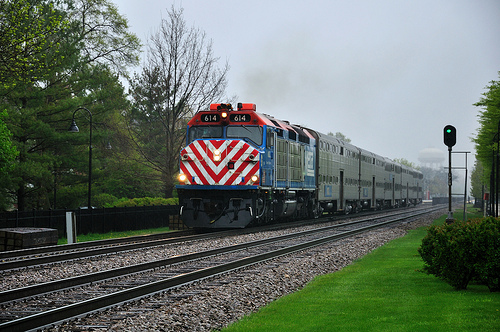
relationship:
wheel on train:
[310, 204, 324, 219] [176, 98, 431, 245]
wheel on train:
[329, 200, 344, 212] [176, 98, 431, 245]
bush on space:
[414, 212, 499, 293] [245, 222, 495, 324]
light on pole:
[446, 126, 453, 136] [440, 121, 459, 221]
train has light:
[172, 102, 424, 228] [217, 109, 228, 121]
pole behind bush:
[440, 121, 459, 221] [419, 214, 499, 291]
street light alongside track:
[68, 104, 93, 209] [0, 196, 453, 330]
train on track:
[162, 77, 272, 227] [117, 260, 147, 299]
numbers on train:
[232, 109, 251, 121] [172, 102, 424, 228]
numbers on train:
[199, 112, 222, 124] [172, 102, 424, 228]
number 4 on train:
[211, 114, 220, 122] [172, 102, 424, 228]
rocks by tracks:
[126, 276, 246, 328] [4, 226, 206, 329]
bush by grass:
[409, 212, 494, 287] [373, 261, 402, 288]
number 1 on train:
[206, 110, 211, 122] [172, 102, 424, 228]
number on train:
[229, 110, 239, 120] [185, 115, 453, 214]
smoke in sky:
[247, 52, 355, 114] [174, 2, 479, 137]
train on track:
[172, 102, 424, 228] [0, 201, 437, 270]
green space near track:
[221, 201, 499, 330] [0, 196, 453, 330]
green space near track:
[45, 218, 171, 245] [0, 196, 453, 330]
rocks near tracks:
[0, 203, 470, 329] [0, 197, 467, 329]